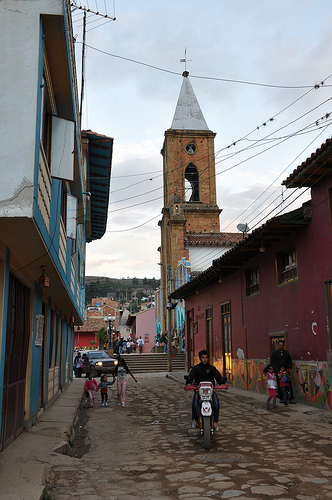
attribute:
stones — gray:
[126, 392, 191, 449]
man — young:
[183, 345, 230, 388]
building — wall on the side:
[169, 109, 220, 296]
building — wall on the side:
[161, 126, 231, 295]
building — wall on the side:
[166, 222, 321, 397]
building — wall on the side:
[151, 170, 319, 415]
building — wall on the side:
[166, 123, 321, 405]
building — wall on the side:
[165, 159, 321, 405]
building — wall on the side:
[165, 50, 222, 270]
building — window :
[151, 68, 218, 272]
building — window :
[178, 158, 206, 200]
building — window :
[279, 246, 301, 280]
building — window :
[236, 261, 267, 292]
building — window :
[46, 316, 55, 366]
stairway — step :
[134, 360, 155, 365]